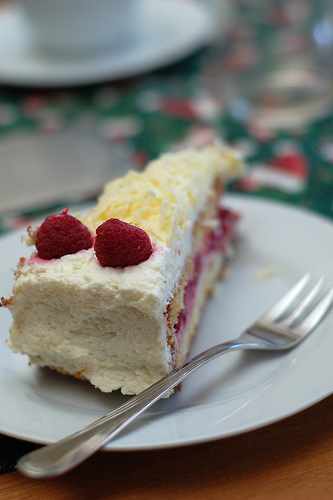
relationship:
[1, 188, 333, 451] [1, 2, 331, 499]
dish on table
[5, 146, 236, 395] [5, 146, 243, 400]
cake in a cake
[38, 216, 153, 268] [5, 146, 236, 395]
berries are on a cake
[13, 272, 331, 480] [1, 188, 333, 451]
fork on a dish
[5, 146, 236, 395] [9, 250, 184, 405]
cake has frosting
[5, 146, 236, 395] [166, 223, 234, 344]
cake has filling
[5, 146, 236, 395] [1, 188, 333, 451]
cake on dish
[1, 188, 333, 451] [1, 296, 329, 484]
dish has a shadow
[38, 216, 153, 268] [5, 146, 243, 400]
berries are on a cake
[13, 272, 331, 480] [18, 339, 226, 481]
fork has a handle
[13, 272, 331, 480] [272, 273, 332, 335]
fork has three tines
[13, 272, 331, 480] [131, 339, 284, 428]
fork has shadow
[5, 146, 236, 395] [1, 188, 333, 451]
cake on a dish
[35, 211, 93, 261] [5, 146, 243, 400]
raspberry on a cake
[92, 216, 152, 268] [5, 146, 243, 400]
berries on a cake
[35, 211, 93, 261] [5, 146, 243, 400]
raspberry on top of a cake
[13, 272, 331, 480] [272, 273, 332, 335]
fork has tines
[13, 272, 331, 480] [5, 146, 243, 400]
fork for cake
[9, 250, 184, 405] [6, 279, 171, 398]
frosting on back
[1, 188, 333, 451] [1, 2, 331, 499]
dish on a table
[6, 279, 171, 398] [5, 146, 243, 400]
back on a cake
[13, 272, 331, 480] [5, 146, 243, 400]
fork by cake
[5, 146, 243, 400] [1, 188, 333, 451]
cake on a dish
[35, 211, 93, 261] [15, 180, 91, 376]
raspberry on left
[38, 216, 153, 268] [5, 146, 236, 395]
berries are on cake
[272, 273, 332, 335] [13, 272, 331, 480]
tines are on fork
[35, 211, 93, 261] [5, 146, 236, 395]
raspberry on cake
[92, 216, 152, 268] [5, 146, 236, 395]
berries of raspberries on cake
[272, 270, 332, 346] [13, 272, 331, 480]
light shining on fork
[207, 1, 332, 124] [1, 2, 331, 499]
glass on table